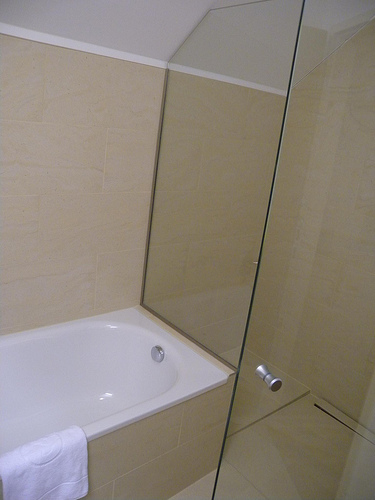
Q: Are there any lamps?
A: No, there are no lamps.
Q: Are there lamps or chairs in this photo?
A: No, there are no lamps or chairs.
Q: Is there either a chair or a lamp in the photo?
A: No, there are no lamps or chairs.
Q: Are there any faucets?
A: No, there are no faucets.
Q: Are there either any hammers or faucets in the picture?
A: No, there are no faucets or hammers.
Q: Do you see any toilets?
A: No, there are no toilets.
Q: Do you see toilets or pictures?
A: No, there are no toilets or pictures.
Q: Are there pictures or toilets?
A: No, there are no toilets or pictures.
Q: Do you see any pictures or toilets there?
A: No, there are no toilets or pictures.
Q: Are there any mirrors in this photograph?
A: No, there are no mirrors.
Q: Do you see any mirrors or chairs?
A: No, there are no mirrors or chairs.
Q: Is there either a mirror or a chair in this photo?
A: No, there are no mirrors or chairs.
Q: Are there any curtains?
A: No, there are no curtains.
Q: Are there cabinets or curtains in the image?
A: No, there are no curtains or cabinets.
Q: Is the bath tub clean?
A: Yes, the bath tub is clean.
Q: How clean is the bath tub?
A: The bath tub is clean.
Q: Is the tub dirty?
A: No, the tub is clean.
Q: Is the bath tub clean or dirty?
A: The bath tub is clean.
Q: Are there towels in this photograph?
A: Yes, there is a towel.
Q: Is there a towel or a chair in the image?
A: Yes, there is a towel.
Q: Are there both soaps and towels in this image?
A: No, there is a towel but no soaps.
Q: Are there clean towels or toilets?
A: Yes, there is a clean towel.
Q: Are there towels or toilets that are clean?
A: Yes, the towel is clean.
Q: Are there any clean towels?
A: Yes, there is a clean towel.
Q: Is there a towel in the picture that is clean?
A: Yes, there is a towel that is clean.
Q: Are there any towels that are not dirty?
A: Yes, there is a clean towel.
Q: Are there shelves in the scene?
A: No, there are no shelves.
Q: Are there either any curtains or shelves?
A: No, there are no shelves or curtains.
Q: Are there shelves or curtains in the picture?
A: No, there are no shelves or curtains.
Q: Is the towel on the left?
A: Yes, the towel is on the left of the image.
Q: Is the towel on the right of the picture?
A: No, the towel is on the left of the image.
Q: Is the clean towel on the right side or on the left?
A: The towel is on the left of the image.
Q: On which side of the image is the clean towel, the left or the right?
A: The towel is on the left of the image.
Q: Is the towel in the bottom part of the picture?
A: Yes, the towel is in the bottom of the image.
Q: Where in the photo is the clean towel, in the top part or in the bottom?
A: The towel is in the bottom of the image.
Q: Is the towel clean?
A: Yes, the towel is clean.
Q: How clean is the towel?
A: The towel is clean.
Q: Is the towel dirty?
A: No, the towel is clean.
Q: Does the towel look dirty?
A: No, the towel is clean.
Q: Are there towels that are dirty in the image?
A: No, there is a towel but it is clean.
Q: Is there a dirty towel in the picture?
A: No, there is a towel but it is clean.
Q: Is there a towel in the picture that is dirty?
A: No, there is a towel but it is clean.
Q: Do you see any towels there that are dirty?
A: No, there is a towel but it is clean.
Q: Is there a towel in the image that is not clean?
A: No, there is a towel but it is clean.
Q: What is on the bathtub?
A: The towel is on the bathtub.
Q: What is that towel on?
A: The towel is on the bathtub.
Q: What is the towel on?
A: The towel is on the bathtub.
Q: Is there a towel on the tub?
A: Yes, there is a towel on the tub.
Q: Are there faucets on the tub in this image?
A: No, there is a towel on the tub.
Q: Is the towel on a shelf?
A: No, the towel is on the bath tub.